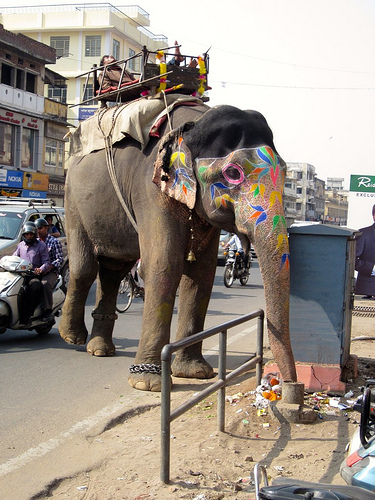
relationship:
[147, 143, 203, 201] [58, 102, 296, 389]
ear of elephant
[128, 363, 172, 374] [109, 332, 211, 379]
chain around ankle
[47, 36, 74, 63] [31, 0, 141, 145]
window on building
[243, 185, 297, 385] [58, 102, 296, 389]
trunk of elephant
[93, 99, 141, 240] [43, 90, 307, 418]
rope around elephant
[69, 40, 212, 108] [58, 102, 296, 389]
carriage on top of elephant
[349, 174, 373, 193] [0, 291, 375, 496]
sign beside ground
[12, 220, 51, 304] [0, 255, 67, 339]
man sitting on bike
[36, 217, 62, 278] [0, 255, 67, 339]
man sitting on bike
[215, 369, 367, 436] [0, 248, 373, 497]
pile on ground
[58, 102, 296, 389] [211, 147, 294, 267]
elephant has painted face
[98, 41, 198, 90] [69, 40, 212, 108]
man in carriage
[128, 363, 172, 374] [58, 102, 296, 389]
chain on elephant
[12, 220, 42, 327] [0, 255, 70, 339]
man on bike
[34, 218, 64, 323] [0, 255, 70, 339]
man on bike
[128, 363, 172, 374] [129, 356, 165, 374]
chain around ankle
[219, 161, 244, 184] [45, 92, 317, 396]
pink eye of elephant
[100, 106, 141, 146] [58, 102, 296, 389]
sheet on top of elephant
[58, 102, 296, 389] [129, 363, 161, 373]
elephant with chain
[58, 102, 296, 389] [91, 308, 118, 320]
elephant with chain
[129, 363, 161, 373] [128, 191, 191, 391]
chain on leg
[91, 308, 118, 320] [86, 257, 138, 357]
chain on leg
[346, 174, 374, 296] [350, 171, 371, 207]
sign with top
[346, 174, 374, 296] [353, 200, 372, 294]
sign with man's picture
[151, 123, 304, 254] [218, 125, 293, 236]
paint on face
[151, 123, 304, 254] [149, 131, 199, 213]
paint on ear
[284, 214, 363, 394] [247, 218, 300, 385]
post next to trunk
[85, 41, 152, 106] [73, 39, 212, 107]
man in carriage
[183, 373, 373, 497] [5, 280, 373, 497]
trash on side of road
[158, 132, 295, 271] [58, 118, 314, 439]
colors painted on elephant